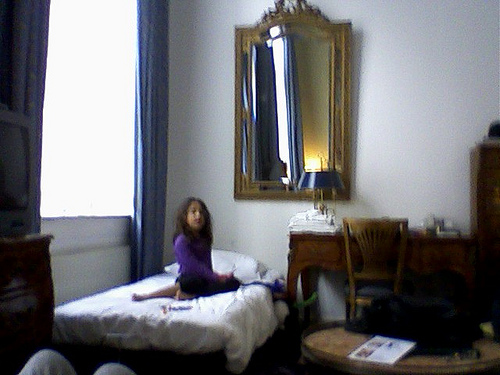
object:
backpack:
[344, 266, 499, 355]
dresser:
[471, 122, 498, 318]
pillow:
[164, 249, 269, 285]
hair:
[170, 196, 212, 249]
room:
[0, 0, 500, 372]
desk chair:
[341, 217, 411, 323]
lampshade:
[294, 168, 347, 192]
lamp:
[295, 169, 345, 213]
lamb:
[302, 152, 331, 174]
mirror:
[230, 0, 354, 204]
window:
[40, 0, 140, 220]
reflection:
[255, 23, 302, 188]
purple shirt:
[173, 229, 220, 282]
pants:
[174, 272, 242, 298]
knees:
[228, 275, 244, 292]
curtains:
[4, 2, 52, 233]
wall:
[165, 0, 500, 277]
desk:
[283, 229, 478, 331]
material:
[346, 332, 416, 367]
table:
[301, 322, 498, 372]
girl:
[130, 195, 241, 302]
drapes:
[132, 0, 170, 284]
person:
[129, 197, 241, 305]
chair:
[338, 216, 410, 334]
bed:
[47, 248, 292, 374]